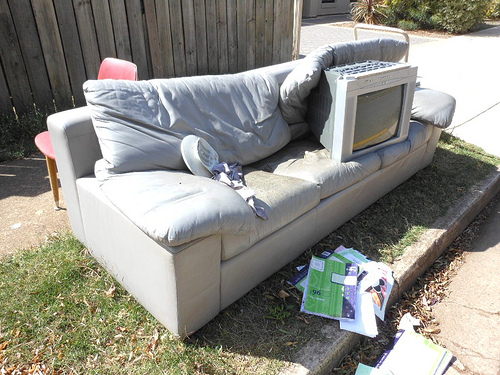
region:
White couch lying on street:
[31, 42, 484, 346]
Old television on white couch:
[313, 54, 423, 168]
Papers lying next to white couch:
[284, 237, 453, 374]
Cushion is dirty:
[214, 143, 330, 260]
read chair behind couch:
[27, 49, 143, 216]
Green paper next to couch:
[289, 244, 349, 329]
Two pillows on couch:
[81, 31, 414, 172]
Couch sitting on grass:
[5, 133, 496, 365]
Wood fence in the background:
[6, 0, 305, 120]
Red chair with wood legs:
[39, 153, 62, 217]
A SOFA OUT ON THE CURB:
[25, 36, 465, 346]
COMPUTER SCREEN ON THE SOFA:
[310, 55, 422, 165]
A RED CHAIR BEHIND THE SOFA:
[31, 56, 142, 214]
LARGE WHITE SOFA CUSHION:
[81, 65, 299, 182]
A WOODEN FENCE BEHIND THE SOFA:
[5, 24, 329, 102]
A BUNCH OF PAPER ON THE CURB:
[289, 240, 465, 372]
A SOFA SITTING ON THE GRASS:
[29, 28, 469, 348]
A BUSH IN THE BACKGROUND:
[386, 1, 493, 37]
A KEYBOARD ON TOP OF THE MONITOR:
[325, 48, 417, 81]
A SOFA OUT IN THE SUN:
[39, 29, 462, 349]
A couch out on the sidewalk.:
[38, 37, 499, 366]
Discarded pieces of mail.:
[295, 242, 467, 374]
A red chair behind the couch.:
[37, 52, 140, 217]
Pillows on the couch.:
[82, 30, 465, 248]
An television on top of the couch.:
[321, 56, 421, 161]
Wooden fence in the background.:
[3, 2, 300, 97]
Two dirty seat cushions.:
[220, 147, 379, 233]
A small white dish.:
[175, 122, 231, 184]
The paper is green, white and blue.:
[302, 247, 363, 328]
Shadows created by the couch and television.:
[183, 131, 495, 361]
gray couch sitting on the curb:
[42, 30, 469, 341]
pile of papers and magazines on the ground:
[288, 241, 466, 372]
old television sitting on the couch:
[300, 50, 422, 167]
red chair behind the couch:
[32, 50, 142, 213]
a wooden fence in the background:
[3, 1, 303, 130]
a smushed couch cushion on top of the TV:
[277, 30, 411, 135]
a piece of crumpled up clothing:
[211, 157, 273, 225]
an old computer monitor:
[302, 57, 426, 167]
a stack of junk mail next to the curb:
[290, 240, 456, 373]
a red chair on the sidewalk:
[34, 50, 145, 212]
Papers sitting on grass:
[306, 244, 393, 374]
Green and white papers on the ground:
[301, 253, 409, 347]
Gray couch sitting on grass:
[29, 28, 439, 336]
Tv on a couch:
[302, 35, 429, 159]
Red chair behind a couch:
[33, 51, 185, 256]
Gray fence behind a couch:
[15, 8, 387, 178]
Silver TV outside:
[309, 48, 465, 175]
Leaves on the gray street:
[371, 243, 461, 357]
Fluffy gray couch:
[51, 48, 280, 238]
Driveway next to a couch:
[306, 17, 486, 174]